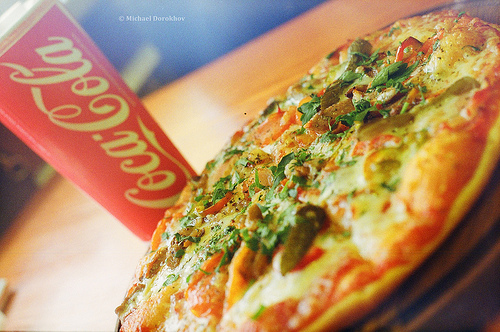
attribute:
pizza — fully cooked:
[309, 131, 406, 240]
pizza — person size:
[114, 13, 482, 330]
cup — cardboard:
[1, 1, 202, 250]